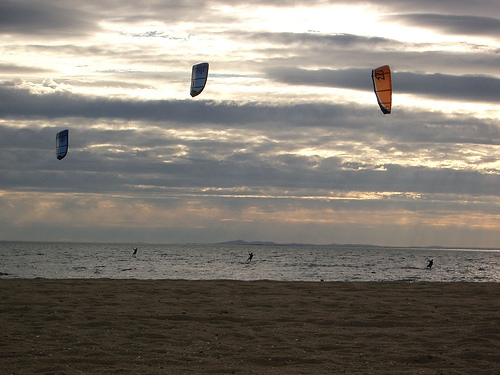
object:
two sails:
[189, 61, 392, 114]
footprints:
[1, 293, 500, 375]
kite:
[189, 62, 209, 98]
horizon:
[0, 230, 499, 284]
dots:
[85, 340, 250, 363]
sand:
[0, 278, 499, 375]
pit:
[131, 331, 173, 339]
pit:
[221, 309, 228, 313]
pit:
[172, 346, 207, 362]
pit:
[243, 352, 337, 370]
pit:
[320, 315, 438, 330]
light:
[92, 68, 174, 105]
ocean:
[0, 240, 500, 282]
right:
[361, 57, 413, 117]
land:
[221, 239, 499, 249]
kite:
[55, 129, 68, 160]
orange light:
[0, 186, 499, 230]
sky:
[0, 0, 499, 249]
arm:
[248, 252, 251, 255]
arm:
[133, 248, 135, 251]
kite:
[371, 64, 392, 115]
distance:
[28, 232, 484, 255]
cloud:
[210, 28, 485, 48]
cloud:
[1, 77, 484, 147]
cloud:
[1, 121, 258, 152]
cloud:
[2, 9, 110, 39]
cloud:
[118, 181, 364, 198]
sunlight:
[276, 147, 348, 159]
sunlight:
[183, 187, 420, 201]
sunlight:
[211, 1, 483, 50]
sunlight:
[3, 32, 287, 52]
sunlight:
[109, 147, 123, 154]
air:
[41, 39, 486, 244]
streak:
[2, 220, 484, 249]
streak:
[0, 199, 484, 226]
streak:
[42, 190, 484, 210]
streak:
[130, 190, 380, 200]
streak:
[1, 148, 483, 189]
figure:
[132, 248, 137, 255]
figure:
[248, 252, 254, 261]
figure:
[426, 259, 432, 269]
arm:
[428, 258, 430, 261]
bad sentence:
[332, 237, 346, 251]